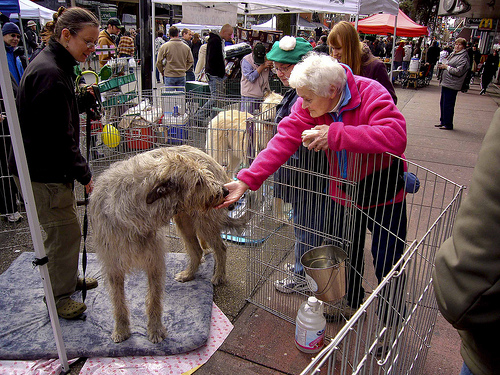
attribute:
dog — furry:
[87, 142, 239, 342]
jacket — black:
[11, 35, 94, 186]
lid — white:
[300, 290, 320, 307]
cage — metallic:
[4, 92, 469, 374]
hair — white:
[284, 52, 353, 102]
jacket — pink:
[232, 65, 410, 209]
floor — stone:
[1, 65, 496, 372]